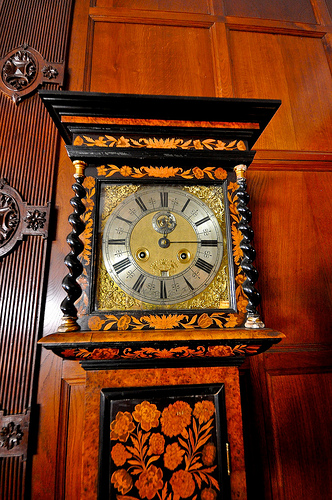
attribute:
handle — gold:
[93, 181, 116, 218]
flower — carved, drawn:
[126, 403, 164, 426]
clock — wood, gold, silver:
[111, 185, 229, 309]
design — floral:
[109, 392, 226, 499]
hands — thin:
[169, 223, 212, 260]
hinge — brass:
[10, 411, 51, 462]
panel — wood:
[177, 6, 312, 86]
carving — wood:
[93, 339, 127, 361]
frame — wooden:
[30, 6, 77, 39]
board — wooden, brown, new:
[122, 90, 165, 115]